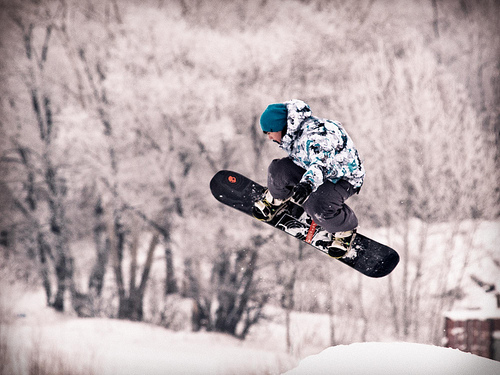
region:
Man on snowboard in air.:
[207, 96, 397, 277]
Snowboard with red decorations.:
[206, 166, 398, 277]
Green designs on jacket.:
[280, 95, 371, 185]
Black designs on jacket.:
[285, 100, 367, 185]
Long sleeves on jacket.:
[282, 97, 363, 192]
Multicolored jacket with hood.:
[285, 95, 370, 190]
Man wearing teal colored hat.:
[250, 92, 362, 257]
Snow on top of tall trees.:
[1, 0, 496, 370]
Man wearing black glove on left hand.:
[258, 96, 366, 260]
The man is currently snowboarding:
[202, 85, 412, 283]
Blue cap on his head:
[259, 99, 289, 134]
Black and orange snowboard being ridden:
[207, 160, 402, 280]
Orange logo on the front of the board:
[225, 170, 237, 183]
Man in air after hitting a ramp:
[201, 88, 404, 285]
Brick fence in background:
[439, 308, 499, 359]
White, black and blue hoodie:
[290, 102, 365, 187]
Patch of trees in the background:
[0, 1, 205, 325]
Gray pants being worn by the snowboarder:
[266, 157, 368, 233]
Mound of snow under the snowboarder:
[262, 338, 498, 373]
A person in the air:
[189, 85, 406, 294]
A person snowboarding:
[200, 73, 425, 303]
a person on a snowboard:
[195, 79, 401, 281]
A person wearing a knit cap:
[242, 99, 317, 150]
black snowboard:
[207, 166, 401, 285]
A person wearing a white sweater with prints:
[240, 90, 372, 187]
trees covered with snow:
[33, 4, 175, 351]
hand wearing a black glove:
[285, 173, 318, 211]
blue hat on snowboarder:
[259, 99, 291, 132]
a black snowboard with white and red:
[205, 168, 400, 278]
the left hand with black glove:
[283, 181, 314, 205]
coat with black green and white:
[282, 93, 365, 190]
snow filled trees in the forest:
[3, 17, 68, 138]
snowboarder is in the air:
[205, 96, 405, 282]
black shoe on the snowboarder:
[323, 230, 353, 261]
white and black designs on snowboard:
[280, 202, 333, 252]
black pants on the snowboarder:
[265, 153, 360, 235]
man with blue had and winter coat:
[254, 97, 371, 187]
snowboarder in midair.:
[201, 96, 404, 286]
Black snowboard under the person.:
[205, 163, 405, 284]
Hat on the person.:
[256, 100, 289, 150]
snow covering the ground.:
[0, 215, 496, 373]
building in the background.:
[437, 300, 497, 360]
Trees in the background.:
[0, 0, 495, 340]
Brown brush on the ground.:
[0, 327, 100, 372]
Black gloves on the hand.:
[286, 177, 311, 203]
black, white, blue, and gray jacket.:
[253, 90, 366, 205]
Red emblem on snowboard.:
[222, 173, 238, 185]